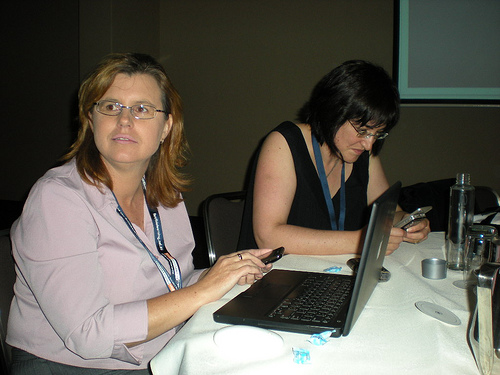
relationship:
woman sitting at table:
[5, 47, 417, 372] [173, 228, 433, 373]